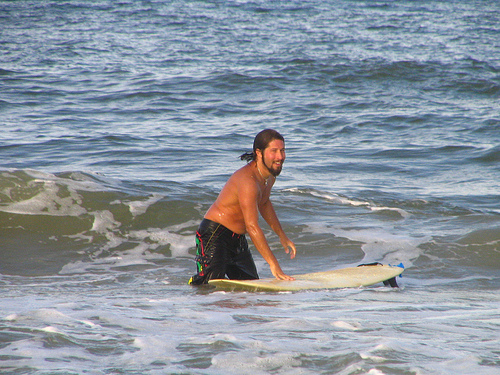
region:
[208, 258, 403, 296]
a white surfboard in the water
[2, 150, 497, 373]
white foamy water in the ocean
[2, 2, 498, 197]
ripples in the blue water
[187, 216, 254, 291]
black board shorts on a surfer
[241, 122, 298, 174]
a brown haired man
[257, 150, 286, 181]
a goatee on a man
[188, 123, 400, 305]
a man surfing in the water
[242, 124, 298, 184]
a man smiling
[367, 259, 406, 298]
black board attachments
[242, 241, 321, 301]
man's hand on the surfboard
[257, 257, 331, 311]
surfboard in the water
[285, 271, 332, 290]
surfboard is yellow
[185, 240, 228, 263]
stripes on man's shorts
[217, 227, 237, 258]
bathing suit is black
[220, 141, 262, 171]
man has a ponytail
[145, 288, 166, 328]
foam on the water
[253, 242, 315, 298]
surfer's hand is on the board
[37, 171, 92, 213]
wave in the ocean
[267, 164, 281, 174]
man has a beard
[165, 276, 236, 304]
man is standing in the ocean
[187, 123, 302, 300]
man with pony tail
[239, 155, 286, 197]
necklace around mans neck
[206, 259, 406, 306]
surfboard floating on water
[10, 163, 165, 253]
sea foam on water top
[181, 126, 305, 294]
man with no shirt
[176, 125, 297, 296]
man wearing black swim trunks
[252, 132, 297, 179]
man with beard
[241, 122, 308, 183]
man smiling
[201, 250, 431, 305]
white surfboard floating on water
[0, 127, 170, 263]
wave in the ocean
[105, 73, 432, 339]
a man in the water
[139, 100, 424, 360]
a man standing in the water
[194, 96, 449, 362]
a man with his hand on a surfboard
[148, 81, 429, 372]
a man standing next to the surfboard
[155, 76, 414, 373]
a man with white surfboard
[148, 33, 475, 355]
a man with surfboard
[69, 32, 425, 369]
a man wearing swim trunks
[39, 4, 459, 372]
a man in a body of water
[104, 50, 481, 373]
a man that is wet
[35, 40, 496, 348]
a body of water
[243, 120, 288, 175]
a head of a man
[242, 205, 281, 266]
the arms of a man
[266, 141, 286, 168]
the face of a man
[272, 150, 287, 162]
the nose of a man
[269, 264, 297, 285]
the hand of a man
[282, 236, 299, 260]
the hand of a man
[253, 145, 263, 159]
the ear of a man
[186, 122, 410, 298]
a man and his surfboard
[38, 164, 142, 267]
a wave in the water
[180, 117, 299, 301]
a man in the water